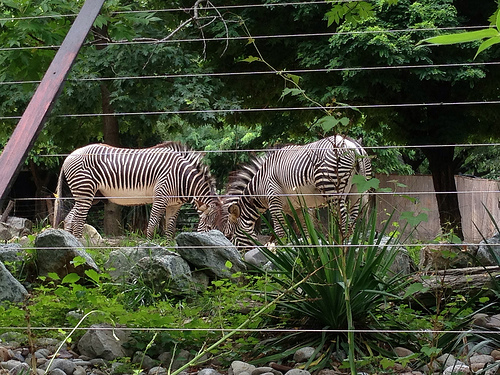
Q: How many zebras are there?
A: Two.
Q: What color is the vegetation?
A: Green.